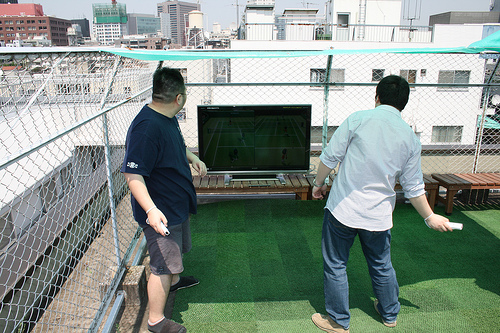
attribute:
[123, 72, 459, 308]
men — playing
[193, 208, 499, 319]
grass — artificial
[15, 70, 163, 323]
fence — linked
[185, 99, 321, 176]
television — flat screen, on, large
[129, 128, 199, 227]
t-shirt — black, dark blue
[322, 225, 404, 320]
jeans — blue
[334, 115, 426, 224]
shirt — white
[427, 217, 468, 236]
control — white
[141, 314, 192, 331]
shoes — black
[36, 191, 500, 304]
roof — fenced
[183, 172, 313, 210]
table — wooden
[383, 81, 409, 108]
hair — dark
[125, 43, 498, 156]
building — tall